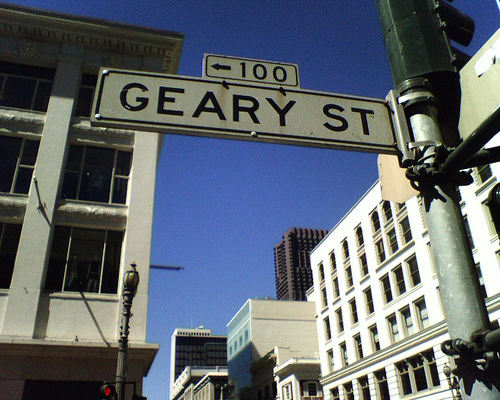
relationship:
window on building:
[391, 302, 418, 333] [298, 131, 499, 398]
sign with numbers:
[197, 46, 304, 91] [237, 59, 288, 84]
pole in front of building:
[352, 10, 498, 389] [4, 14, 188, 399]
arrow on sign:
[203, 62, 245, 87] [87, 40, 412, 160]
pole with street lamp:
[112, 293, 134, 398] [117, 257, 142, 313]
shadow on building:
[31, 240, 122, 347] [4, 14, 188, 399]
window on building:
[367, 325, 377, 351] [293, 157, 483, 397]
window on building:
[331, 276, 341, 297] [298, 131, 499, 398]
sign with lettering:
[74, 41, 417, 172] [113, 80, 378, 136]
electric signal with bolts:
[315, 24, 497, 204] [404, 159, 434, 179]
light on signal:
[79, 252, 163, 397] [97, 378, 138, 398]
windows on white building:
[2, 113, 139, 310] [1, 2, 184, 399]